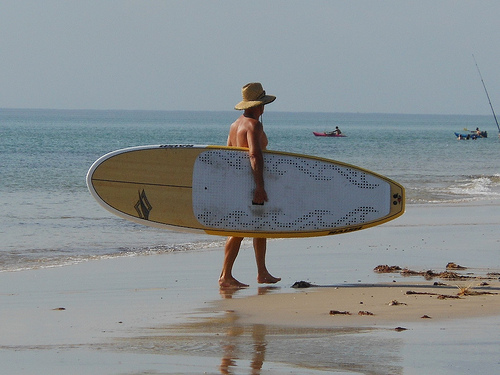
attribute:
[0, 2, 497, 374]
photo — outdoor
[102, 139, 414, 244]
board — white and yellow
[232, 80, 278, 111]
straw hat — on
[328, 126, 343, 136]
woman — on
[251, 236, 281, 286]
leg — of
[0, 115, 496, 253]
ocean — blue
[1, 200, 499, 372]
sand — wet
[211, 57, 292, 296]
man — on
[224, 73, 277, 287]
man — on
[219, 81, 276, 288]
man — with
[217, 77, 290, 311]
man — on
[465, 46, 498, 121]
pole — tall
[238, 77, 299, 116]
head — of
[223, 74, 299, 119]
hat — on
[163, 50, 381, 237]
man — surfer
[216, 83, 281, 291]
man — on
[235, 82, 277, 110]
hat — of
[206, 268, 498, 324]
sand — dry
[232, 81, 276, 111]
sunhat — brown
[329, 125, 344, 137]
man — in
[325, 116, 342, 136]
people — on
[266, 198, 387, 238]
design — on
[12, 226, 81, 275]
ocean — on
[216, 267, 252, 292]
foot — of